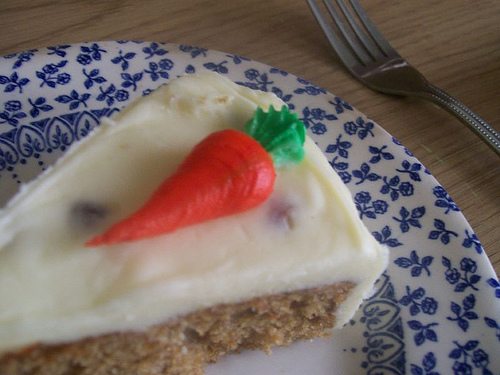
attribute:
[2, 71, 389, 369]
cake — frosted, brown, slice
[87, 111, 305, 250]
carrot — green, orange, icing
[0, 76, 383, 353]
top — white, orange, cream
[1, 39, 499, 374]
dish — blue, wood, decorated, patterned, white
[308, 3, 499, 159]
fork — silver, metal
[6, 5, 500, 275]
table — wood, brown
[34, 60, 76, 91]
flower — blue